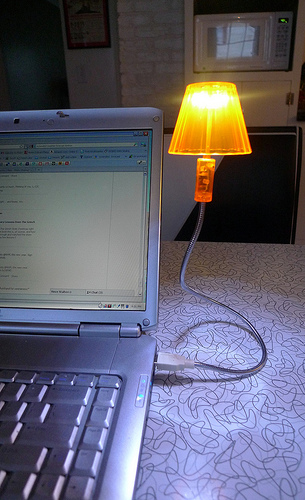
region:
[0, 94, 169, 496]
A computer laptop in the foreground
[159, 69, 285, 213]
A small computer lamp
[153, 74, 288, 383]
Lamp is orange in color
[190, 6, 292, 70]
A microwave in the background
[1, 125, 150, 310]
Laptop screen is on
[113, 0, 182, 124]
White colored brick in the background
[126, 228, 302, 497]
Laptop is on a white table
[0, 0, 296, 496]
Photo was taken indoors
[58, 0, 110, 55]
A poster is on the wall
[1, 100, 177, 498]
The laptop is silver in color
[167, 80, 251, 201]
Small orange light with shade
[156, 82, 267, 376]
Small orange light plugged into laptop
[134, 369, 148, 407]
Lights on side of laptop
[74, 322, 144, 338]
Silver hinge on back of laptop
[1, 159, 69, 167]
Icons on computer screen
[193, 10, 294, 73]
White microwave in cabinet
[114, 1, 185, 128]
White bricks on kitchen wall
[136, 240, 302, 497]
Sqiggly pattern on top of table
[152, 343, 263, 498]
Reflection from light on top of table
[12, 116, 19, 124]
Camera on top of laptop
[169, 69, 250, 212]
lamp is turned on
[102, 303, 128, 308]
small icons on the bottom of the laptop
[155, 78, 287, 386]
light is plugged into the computer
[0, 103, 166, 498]
silver laptop that is turned on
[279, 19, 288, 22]
green numbers on the microwave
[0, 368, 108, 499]
silver keys on the laptop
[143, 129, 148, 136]
red and white close button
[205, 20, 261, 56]
reflection on the microwave door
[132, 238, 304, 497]
design on the table top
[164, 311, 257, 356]
shadow from the wire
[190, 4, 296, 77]
this room has a microwave oven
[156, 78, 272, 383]
this wicked cool little light gets power from the computer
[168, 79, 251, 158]
the wicked cool little light has a gold shade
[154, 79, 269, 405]
the wicked cool little light is plugged into the computer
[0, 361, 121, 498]
the laptop has silver keys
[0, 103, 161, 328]
the laptop is turned on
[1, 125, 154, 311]
the screen has a blue color scheme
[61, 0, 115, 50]
a picture hangs on the wall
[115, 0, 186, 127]
this wall is made of brick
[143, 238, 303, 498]
the pattern on the table kind of looks like scribbles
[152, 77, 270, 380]
yellow USB powered LED light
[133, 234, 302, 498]
boomerang patterned surface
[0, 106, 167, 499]
silver plastic lap top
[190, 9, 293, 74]
shiny white plastic microwave front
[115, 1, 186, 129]
white painted brick wall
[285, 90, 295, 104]
brass metal door hinge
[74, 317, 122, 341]
silver plastic lap top hinge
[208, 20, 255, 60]
reflection of a glass paned window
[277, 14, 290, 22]
green digital microwave clock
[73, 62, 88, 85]
rectangular white light switch